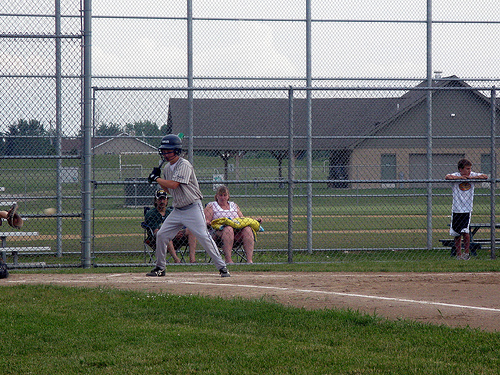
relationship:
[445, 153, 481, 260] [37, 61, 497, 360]
boy watching baseball game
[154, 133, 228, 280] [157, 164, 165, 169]
player with bat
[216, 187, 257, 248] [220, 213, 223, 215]
lady wearing yellow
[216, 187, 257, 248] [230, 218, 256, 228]
lady holding blanket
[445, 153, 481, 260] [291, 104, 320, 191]
boy looking through fence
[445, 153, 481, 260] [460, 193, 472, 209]
boy has shirt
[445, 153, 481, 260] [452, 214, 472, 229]
boy wearing shorts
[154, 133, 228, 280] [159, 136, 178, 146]
player wearing helmet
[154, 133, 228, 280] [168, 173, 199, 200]
player has shirt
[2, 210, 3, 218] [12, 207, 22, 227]
person has catcher's mitt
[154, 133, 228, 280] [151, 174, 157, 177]
player has hand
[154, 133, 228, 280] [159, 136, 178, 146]
player has helmet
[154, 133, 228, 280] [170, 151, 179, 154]
player has head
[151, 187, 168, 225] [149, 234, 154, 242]
person sitting in chair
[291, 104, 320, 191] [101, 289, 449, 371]
fence behind field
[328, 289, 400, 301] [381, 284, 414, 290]
line in dirt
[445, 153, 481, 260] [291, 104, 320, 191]
boy leaning on fence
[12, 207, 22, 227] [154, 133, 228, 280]
catcher's mitt behind player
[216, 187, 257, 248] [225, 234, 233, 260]
lady has leg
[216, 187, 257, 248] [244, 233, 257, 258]
lady has leg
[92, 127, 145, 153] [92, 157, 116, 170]
building behind hill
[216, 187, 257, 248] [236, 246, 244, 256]
lady sitting in chair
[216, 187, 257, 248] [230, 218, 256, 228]
lady with blanket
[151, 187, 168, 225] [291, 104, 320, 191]
person behind fence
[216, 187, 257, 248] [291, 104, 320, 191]
lady behind fence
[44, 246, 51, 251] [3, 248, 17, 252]
edge of bleacher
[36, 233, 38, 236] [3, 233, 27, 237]
edge of bleacher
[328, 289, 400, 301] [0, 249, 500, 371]
line on field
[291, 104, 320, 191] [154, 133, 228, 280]
fence behind player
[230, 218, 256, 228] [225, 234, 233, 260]
blanket on leg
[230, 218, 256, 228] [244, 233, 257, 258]
blanket on leg